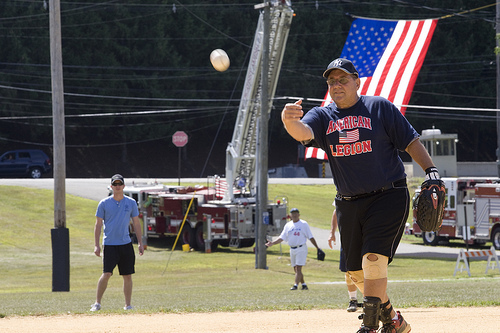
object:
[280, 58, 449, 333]
man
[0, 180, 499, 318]
grass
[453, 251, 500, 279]
barricades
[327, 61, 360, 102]
head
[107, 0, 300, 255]
firetruck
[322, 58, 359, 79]
baseball cap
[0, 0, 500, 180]
pitch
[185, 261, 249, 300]
ground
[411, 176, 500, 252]
truck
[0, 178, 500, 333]
field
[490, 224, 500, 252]
wheel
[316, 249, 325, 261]
baseball glove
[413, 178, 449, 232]
baseball glove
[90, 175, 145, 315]
man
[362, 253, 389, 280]
brace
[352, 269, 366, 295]
brace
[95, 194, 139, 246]
shirt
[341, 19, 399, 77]
part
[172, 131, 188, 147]
sign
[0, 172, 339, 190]
road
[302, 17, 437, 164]
american flag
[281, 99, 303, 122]
hand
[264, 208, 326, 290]
man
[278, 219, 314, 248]
t-shirt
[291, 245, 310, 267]
pants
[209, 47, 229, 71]
ball